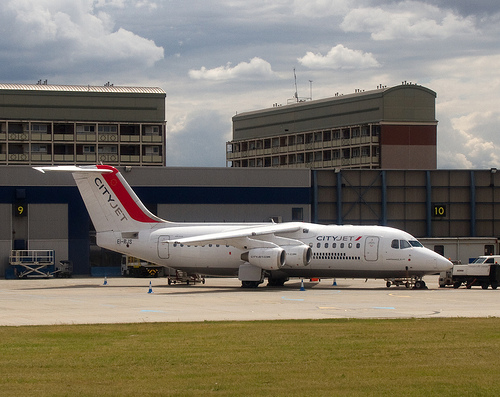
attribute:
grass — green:
[107, 320, 419, 393]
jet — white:
[24, 153, 458, 293]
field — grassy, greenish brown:
[2, 317, 500, 390]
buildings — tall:
[4, 75, 444, 164]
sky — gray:
[2, 4, 491, 83]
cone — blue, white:
[97, 270, 159, 298]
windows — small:
[7, 119, 168, 158]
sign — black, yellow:
[430, 200, 450, 216]